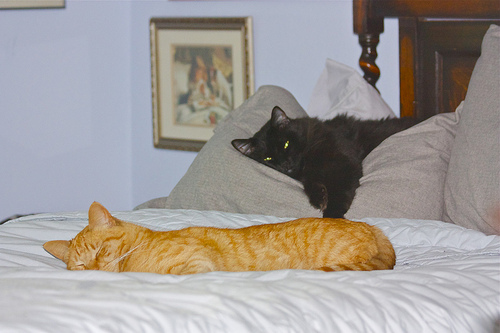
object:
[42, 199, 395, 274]
cat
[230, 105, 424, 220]
cat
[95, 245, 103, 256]
eye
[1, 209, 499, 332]
comforter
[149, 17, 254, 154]
picture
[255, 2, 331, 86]
wall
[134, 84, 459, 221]
pillow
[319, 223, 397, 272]
tail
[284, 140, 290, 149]
eye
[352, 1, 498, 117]
headboard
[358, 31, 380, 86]
spinal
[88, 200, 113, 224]
ear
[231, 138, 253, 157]
ear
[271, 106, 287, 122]
ear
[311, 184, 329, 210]
paw